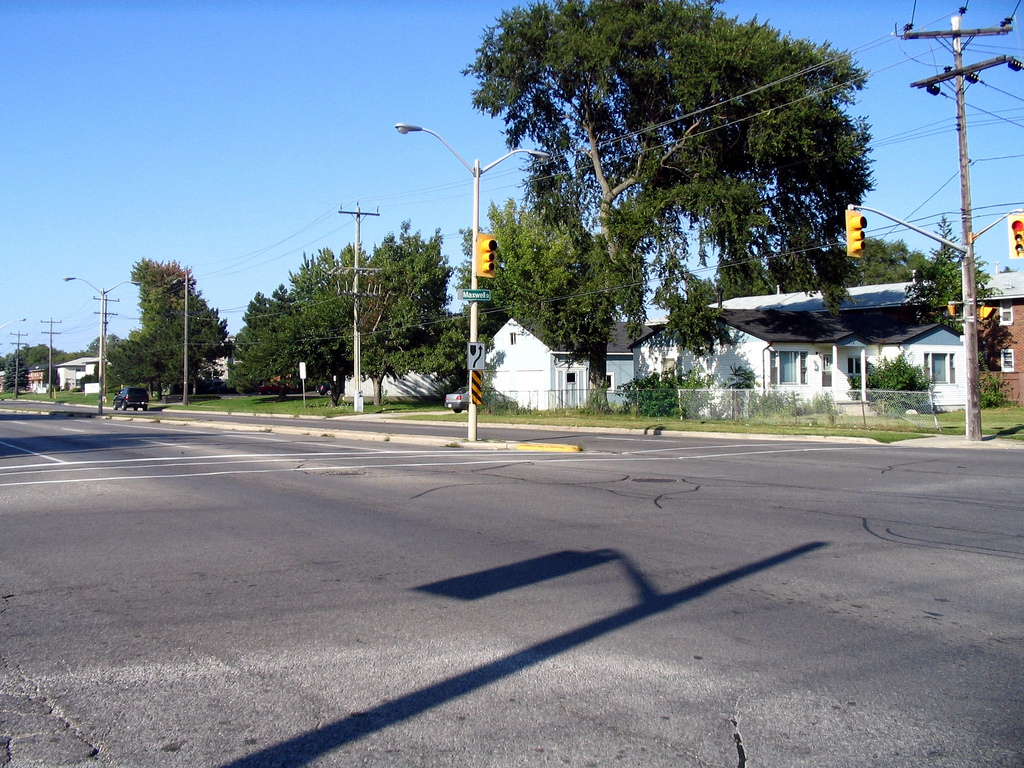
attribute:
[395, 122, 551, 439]
street light — off, silver, tall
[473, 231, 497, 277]
traffic light casing — yellow, hanging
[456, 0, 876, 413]
tree — large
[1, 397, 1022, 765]
street — grey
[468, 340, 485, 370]
sign — black, white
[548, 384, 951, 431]
fence — metal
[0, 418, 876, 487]
lines — white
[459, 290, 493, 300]
street sign — green, white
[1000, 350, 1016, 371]
window — small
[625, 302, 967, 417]
house — white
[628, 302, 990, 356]
rooftop — black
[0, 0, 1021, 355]
sky — blue